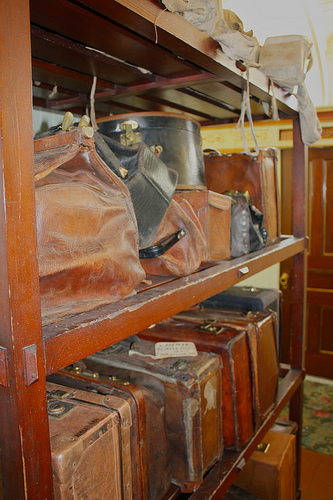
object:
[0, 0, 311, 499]
wooden rack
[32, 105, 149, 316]
luggage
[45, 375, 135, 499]
luggage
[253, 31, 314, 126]
bag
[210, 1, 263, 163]
bag